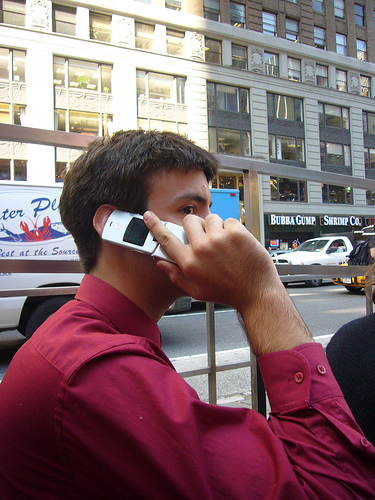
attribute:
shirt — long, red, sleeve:
[0, 261, 357, 492]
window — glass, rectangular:
[262, 50, 280, 75]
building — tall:
[1, 1, 374, 255]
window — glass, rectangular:
[232, 3, 247, 27]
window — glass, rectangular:
[334, 69, 349, 93]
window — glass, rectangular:
[336, 34, 350, 58]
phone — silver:
[98, 205, 207, 265]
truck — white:
[0, 175, 93, 344]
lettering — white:
[266, 212, 362, 229]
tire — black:
[20, 292, 80, 342]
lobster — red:
[14, 212, 63, 245]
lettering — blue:
[0, 245, 75, 257]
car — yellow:
[328, 242, 373, 300]